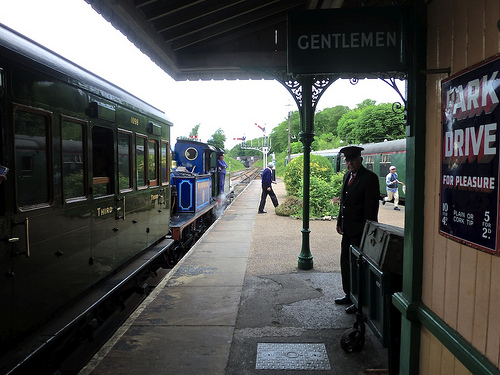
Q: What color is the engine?
A: Blue.